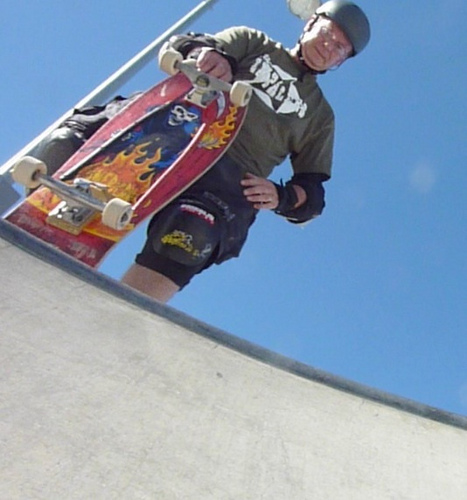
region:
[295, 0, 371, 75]
man wearing a gray safety helmet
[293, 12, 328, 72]
black chin strap of helmet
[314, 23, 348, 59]
man wearing glasses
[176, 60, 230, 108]
gray metal trucks on skateboard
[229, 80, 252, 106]
white wheels on skateboard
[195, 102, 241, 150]
flame graphic on skateboard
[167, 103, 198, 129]
skull face on skateboard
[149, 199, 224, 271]
black knee pad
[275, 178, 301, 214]
man wearing black wrist guards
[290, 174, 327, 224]
black elbow pad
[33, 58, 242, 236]
skateboard is red and orange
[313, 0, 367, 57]
man wears green helmet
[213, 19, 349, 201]
man wears grey shirt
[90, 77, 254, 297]
man wears black shorts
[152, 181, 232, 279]
man wears knee pads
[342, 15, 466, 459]
sky is blue and cloudless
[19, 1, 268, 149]
pole behind man skateboarding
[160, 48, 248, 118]
skateboard has white wheels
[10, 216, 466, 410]
ramp has black lip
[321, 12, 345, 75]
man is wearing eyeglasses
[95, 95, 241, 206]
the skate board has red flames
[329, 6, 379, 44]
the helmet is grey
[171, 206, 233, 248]
the kneepads are black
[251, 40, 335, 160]
the shirt is grey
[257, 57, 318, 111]
the picture is white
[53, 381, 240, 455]
the surface is white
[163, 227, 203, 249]
pictures are on the kneepads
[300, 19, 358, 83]
the guy is wearing glasses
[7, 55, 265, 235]
the wheels are four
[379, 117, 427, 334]
the sky has no clouds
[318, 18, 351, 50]
The eyeglasses on the man's face.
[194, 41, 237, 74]
The guy's hand on the skateboard.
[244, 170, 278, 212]
The guy's hand on his hip.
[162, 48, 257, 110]
The front wheels of the skateboard.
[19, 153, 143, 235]
The back wheels of the skateboard.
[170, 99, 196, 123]
The face of the skeleton on the bottom of the skateboard.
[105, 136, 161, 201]
The flames near the bottom of the skateboard.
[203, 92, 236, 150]
The flames towards the top of the skateboard.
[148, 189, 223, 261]
The knee pad on the man's knee.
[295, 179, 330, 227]
The elbow pad on the man's elbow.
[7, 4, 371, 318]
Old man contemplating skate boarding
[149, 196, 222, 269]
Black knee pad with yellow, white, and purple lettering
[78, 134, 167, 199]
Orange and red flames painted on back of skate board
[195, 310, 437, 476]
Ridge of steep ramp heading in downard direction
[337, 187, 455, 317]
Portion of clear blue sky day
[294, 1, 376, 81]
Old man wearing a dark green helmet with black straps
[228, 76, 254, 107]
White skate board wheel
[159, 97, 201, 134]
White skull face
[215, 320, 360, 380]
Navy blue trim of skateboarding ramp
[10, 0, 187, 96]
Section of gray metal pole